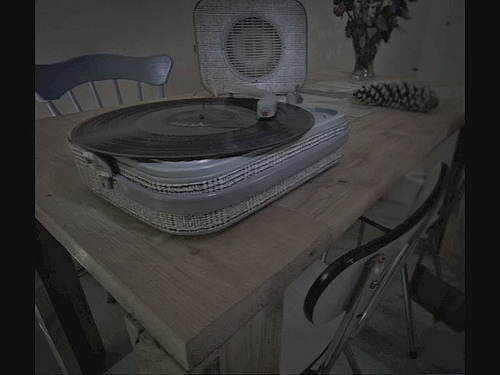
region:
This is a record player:
[56, 69, 351, 247]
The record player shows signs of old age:
[43, 70, 367, 244]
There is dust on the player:
[65, 76, 342, 243]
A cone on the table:
[349, 60, 448, 125]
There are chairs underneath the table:
[266, 160, 457, 373]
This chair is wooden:
[37, 36, 194, 112]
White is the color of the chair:
[37, 32, 184, 109]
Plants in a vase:
[326, 2, 427, 83]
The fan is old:
[190, 3, 352, 103]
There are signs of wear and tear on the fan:
[181, 2, 331, 97]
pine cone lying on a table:
[342, 50, 469, 183]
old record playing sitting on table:
[60, 97, 381, 242]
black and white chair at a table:
[291, 132, 477, 373]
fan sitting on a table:
[177, 3, 366, 115]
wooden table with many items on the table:
[64, 53, 450, 350]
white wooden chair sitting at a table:
[25, 30, 300, 157]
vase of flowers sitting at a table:
[324, 0, 460, 102]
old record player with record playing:
[57, 77, 384, 252]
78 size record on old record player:
[61, 91, 371, 223]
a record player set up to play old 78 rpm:
[54, 77, 364, 250]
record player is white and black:
[55, 74, 398, 262]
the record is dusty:
[58, 79, 303, 185]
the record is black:
[70, 91, 284, 191]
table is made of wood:
[30, 103, 479, 308]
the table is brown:
[21, 93, 498, 345]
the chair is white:
[30, 40, 170, 140]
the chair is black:
[273, 134, 498, 313]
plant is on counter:
[330, 3, 396, 84]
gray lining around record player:
[109, 171, 234, 228]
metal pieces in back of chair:
[355, 269, 382, 354]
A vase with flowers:
[326, 1, 411, 83]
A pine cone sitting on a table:
[338, 70, 455, 131]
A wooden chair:
[35, 42, 184, 117]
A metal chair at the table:
[297, 153, 479, 365]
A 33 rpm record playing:
[67, 89, 324, 169]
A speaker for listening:
[188, 5, 316, 105]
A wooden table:
[34, 80, 480, 374]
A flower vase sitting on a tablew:
[328, 4, 403, 100]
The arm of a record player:
[203, 72, 295, 126]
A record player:
[64, 124, 347, 244]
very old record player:
[11, 36, 357, 304]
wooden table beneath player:
[56, 273, 285, 348]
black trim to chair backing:
[324, 161, 454, 278]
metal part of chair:
[314, 205, 448, 342]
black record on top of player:
[77, 70, 288, 192]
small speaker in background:
[176, 6, 328, 93]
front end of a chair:
[7, 37, 182, 113]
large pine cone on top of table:
[345, 74, 438, 114]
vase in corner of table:
[340, 4, 390, 91]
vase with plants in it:
[319, 0, 421, 93]